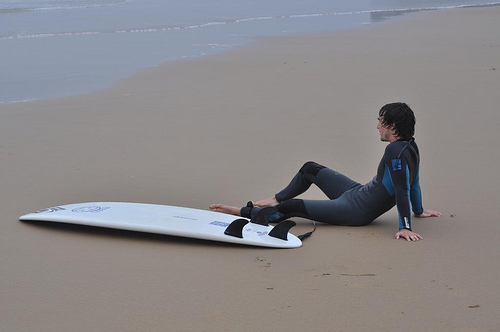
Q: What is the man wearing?
A: A wet suit.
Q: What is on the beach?
A: The surfer.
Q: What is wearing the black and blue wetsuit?
A: The surfer.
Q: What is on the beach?
A: The surf board.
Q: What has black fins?
A: The white surfboard.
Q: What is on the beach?
A: White surfboard and black fins.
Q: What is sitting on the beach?
A: The man in the wetsuit.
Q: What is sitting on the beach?
A: The man in the black and blue wetsuit.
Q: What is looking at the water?
A: The man.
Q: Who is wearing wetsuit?
A: Surfer.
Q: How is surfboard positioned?
A: Upside down.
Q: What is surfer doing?
A: Resting.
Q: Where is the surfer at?
A: The beach.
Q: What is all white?
A: Surfboard.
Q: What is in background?
A: Ocean.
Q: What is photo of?
A: Surfer by water.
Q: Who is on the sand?
A: A man.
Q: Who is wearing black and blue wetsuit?
A: Surfer guy.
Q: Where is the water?
A: Near the sand.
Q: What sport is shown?
A: Surfing.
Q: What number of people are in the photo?
A: 1.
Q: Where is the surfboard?
A: Next to the man, on the sand.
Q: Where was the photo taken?
A: Beach.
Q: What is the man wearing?
A: Wetsuit.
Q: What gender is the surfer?
A: Male.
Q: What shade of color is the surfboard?
A: White.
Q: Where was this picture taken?
A: On the beach.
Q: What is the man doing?
A: Sitting.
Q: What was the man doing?
A: Surfing.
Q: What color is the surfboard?
A: White.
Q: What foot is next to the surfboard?
A: Left foot.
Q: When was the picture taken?
A: Daytime.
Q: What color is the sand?
A: Brown.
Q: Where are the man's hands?
A: Behind him.